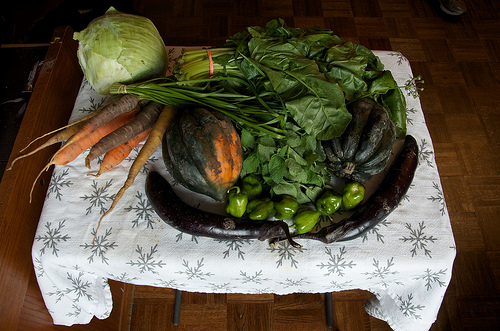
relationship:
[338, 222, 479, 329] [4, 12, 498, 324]
towel on table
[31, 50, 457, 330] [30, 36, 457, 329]
tablecloth on table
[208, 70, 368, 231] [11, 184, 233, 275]
spinach on cloth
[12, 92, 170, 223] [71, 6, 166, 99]
carrots by lettuce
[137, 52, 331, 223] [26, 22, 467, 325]
vegetables on cloth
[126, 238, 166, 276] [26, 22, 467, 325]
snowflake on cloth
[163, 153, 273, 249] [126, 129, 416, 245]
vegetable by peppers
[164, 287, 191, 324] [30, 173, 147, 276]
table leg on table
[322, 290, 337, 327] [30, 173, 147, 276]
table leg on table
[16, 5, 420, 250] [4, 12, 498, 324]
fruit sitting on table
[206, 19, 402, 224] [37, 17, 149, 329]
greens on table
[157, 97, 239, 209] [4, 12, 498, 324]
squash on table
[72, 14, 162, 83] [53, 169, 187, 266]
cabbage on table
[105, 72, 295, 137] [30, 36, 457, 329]
onion on table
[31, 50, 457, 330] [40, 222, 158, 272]
tablecloth with snowflake pattern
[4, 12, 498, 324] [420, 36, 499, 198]
table on floor of wooden squares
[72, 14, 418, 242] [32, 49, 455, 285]
vegetables on table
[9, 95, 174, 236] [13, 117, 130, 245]
carrots with roots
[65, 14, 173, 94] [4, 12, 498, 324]
cabbage on table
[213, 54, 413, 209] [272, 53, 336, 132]
leaves with center stem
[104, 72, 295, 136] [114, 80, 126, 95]
scallions tied with bands